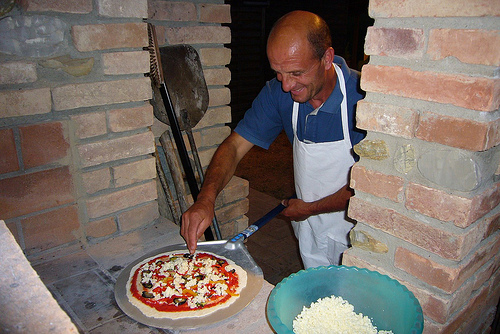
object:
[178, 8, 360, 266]
man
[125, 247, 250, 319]
pizza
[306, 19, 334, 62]
hair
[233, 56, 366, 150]
shirt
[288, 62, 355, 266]
apron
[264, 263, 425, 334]
bowl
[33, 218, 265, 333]
stone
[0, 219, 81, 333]
brick oven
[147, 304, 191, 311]
red tomato sauce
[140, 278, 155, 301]
black olives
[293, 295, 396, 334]
cheese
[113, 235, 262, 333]
pizza peel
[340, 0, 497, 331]
post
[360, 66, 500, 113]
brick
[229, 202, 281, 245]
handle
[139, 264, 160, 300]
vegetable toppings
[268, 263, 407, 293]
edge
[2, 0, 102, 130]
part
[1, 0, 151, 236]
wall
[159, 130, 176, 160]
part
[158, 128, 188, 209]
stick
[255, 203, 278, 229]
part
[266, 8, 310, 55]
no hair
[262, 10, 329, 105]
head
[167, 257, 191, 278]
cheese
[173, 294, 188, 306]
mushroom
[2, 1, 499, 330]
pizzeria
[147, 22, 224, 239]
baking tool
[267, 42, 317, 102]
face